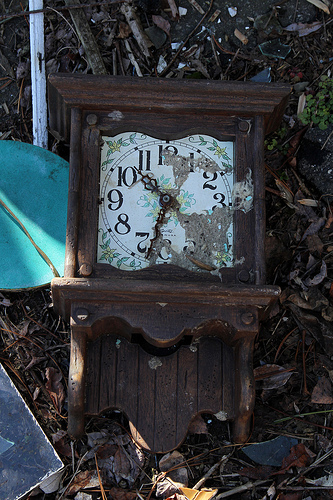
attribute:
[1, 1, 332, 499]
leaves are brown — dry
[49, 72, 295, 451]
turqoise object — turquoise , wooden, damaged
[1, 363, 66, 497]
piece of glass — broken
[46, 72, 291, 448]
piece of wood — white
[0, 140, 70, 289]
teal plate — round, dirty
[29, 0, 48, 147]
white pole — brown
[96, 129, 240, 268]
time reads 10:35 — black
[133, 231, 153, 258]
number seven — curly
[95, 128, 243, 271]
web-like material — thick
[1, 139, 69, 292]
blue object — round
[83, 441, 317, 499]
leaves — brown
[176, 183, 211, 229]
pattern — floral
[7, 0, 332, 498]
leaves — dry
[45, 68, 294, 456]
clock — broken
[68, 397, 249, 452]
design — curved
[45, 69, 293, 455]
frame — wooden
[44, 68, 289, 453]
case — curved, wooden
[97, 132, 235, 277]
clock — wood, brown, wooden, old, dirty, white, discarded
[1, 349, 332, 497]
leaves — dried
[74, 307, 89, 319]
peg — wooden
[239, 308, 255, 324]
peg — wooden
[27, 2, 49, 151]
molding — thin, white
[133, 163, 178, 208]
hand — black, dainty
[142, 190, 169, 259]
hand — black, dainty